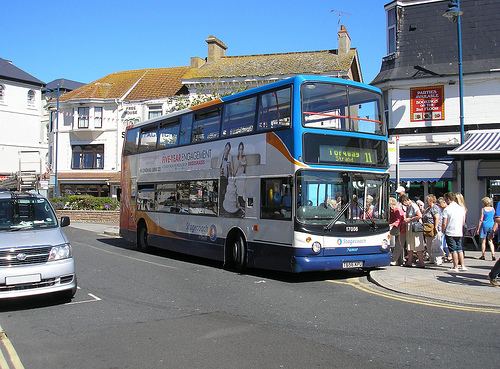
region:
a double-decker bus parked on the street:
[117, 73, 396, 275]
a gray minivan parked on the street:
[1, 187, 73, 307]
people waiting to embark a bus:
[388, 185, 467, 273]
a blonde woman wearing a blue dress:
[476, 197, 496, 262]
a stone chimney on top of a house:
[204, 38, 229, 59]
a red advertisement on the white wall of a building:
[409, 85, 444, 124]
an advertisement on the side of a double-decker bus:
[128, 133, 267, 218]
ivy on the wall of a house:
[166, 79, 266, 112]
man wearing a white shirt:
[442, 203, 465, 236]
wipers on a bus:
[324, 195, 378, 234]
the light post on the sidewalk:
[444, 0, 464, 200]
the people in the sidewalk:
[388, 183, 498, 284]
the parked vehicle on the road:
[0, 188, 78, 305]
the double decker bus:
[120, 75, 390, 273]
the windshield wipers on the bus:
[326, 200, 377, 230]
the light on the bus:
[312, 241, 322, 251]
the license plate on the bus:
[342, 260, 363, 267]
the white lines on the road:
[60, 227, 175, 304]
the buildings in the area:
[2, 0, 498, 245]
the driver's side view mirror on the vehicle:
[60, 214, 70, 226]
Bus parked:
[116, 72, 395, 278]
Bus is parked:
[110, 69, 396, 277]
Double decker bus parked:
[112, 70, 397, 279]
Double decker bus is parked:
[110, 70, 396, 277]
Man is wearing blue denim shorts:
[442, 230, 465, 255]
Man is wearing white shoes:
[446, 260, 471, 277]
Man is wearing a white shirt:
[441, 195, 466, 239]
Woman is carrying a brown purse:
[420, 217, 438, 237]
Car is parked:
[0, 160, 87, 312]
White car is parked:
[0, 148, 80, 315]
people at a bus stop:
[390, 185, 468, 274]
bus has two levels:
[119, 73, 391, 274]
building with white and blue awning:
[448, 128, 499, 159]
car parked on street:
[0, 190, 78, 302]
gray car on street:
[1, 187, 76, 302]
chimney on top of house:
[176, 24, 358, 109]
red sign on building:
[409, 83, 446, 121]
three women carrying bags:
[388, 190, 444, 267]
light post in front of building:
[442, 0, 465, 270]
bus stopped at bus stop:
[118, 73, 393, 272]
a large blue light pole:
[441, 1, 468, 196]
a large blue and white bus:
[122, 75, 392, 281]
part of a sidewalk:
[372, 253, 499, 301]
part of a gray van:
[0, 185, 75, 312]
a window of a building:
[76, 106, 89, 128]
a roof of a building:
[190, 51, 347, 75]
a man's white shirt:
[440, 199, 466, 239]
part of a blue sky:
[0, 0, 211, 42]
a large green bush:
[83, 195, 118, 210]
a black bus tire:
[225, 227, 251, 274]